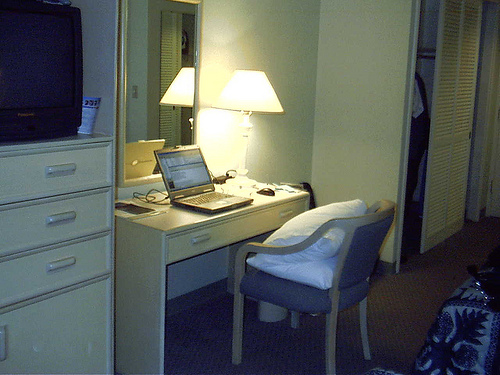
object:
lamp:
[209, 69, 287, 187]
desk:
[111, 173, 312, 374]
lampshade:
[158, 67, 196, 130]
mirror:
[124, 0, 197, 179]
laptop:
[151, 147, 253, 215]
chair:
[228, 199, 396, 374]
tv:
[0, 0, 83, 149]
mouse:
[255, 187, 276, 198]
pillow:
[244, 256, 342, 291]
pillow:
[256, 198, 366, 264]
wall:
[114, 0, 320, 201]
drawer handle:
[40, 161, 78, 176]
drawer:
[0, 142, 109, 204]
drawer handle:
[46, 209, 75, 227]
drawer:
[0, 187, 111, 256]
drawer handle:
[47, 255, 77, 272]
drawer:
[0, 227, 111, 307]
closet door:
[419, 1, 486, 256]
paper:
[75, 96, 101, 134]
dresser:
[0, 134, 116, 375]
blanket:
[364, 258, 499, 375]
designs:
[441, 308, 491, 348]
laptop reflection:
[119, 137, 165, 180]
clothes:
[408, 77, 424, 121]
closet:
[393, 1, 485, 273]